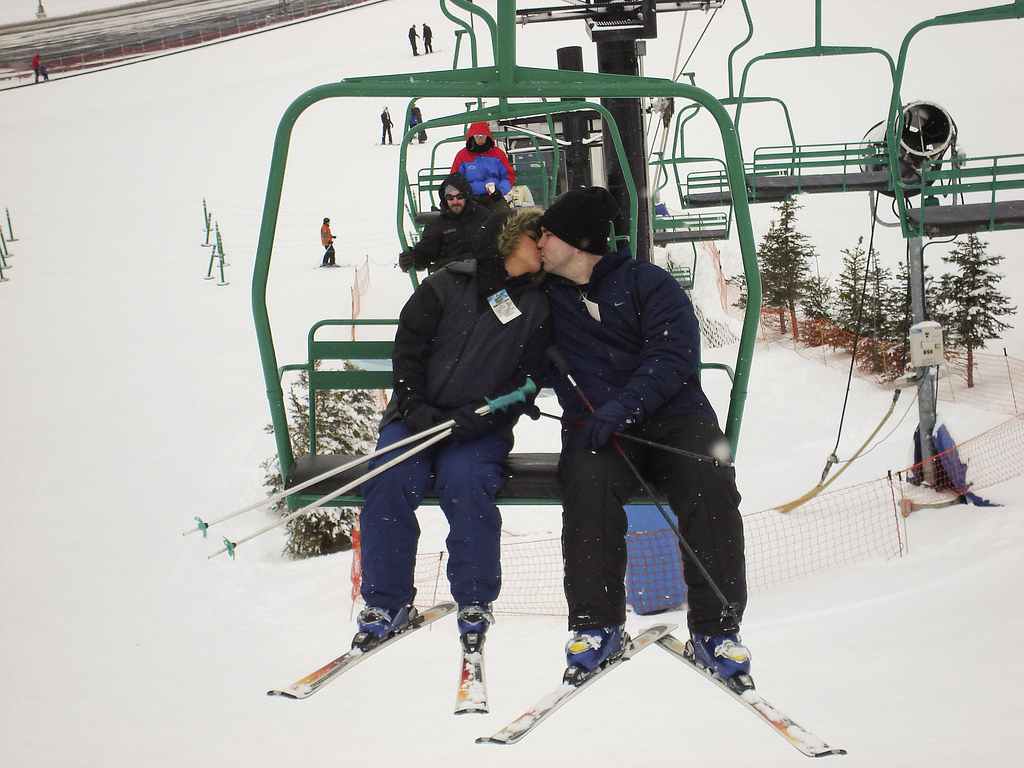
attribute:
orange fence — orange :
[342, 250, 994, 628]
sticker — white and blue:
[486, 289, 516, 310]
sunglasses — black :
[440, 187, 469, 204]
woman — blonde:
[348, 200, 555, 654]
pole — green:
[215, 238, 235, 290]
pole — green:
[202, 240, 229, 273]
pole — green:
[199, 203, 225, 251]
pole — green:
[202, 197, 213, 235]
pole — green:
[0, 206, 21, 244]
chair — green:
[840, 47, 1021, 355]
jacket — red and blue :
[432, 132, 521, 216]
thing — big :
[846, 80, 998, 191]